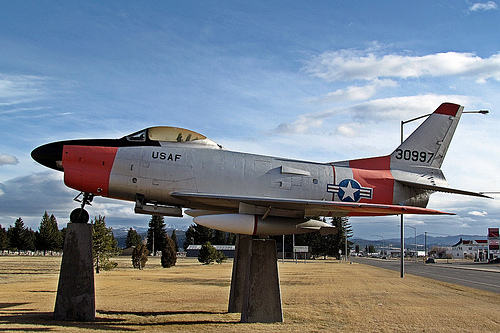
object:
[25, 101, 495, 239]
plane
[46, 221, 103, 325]
pillar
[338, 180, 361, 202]
star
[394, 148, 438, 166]
number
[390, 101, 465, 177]
tail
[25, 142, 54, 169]
nose tip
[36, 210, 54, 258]
tree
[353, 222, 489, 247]
mountains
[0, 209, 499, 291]
background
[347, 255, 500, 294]
road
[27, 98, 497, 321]
display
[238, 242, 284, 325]
column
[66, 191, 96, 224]
front landing gear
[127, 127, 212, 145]
dome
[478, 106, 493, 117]
street light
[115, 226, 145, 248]
mountain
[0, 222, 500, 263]
distance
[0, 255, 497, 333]
park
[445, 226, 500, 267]
town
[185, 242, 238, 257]
barn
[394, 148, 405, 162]
3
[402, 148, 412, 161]
0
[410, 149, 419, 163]
9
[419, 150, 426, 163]
9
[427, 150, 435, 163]
7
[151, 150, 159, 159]
u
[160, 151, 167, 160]
s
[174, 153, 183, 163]
f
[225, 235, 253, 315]
post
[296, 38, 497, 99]
cloud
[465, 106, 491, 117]
post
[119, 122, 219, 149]
cockpit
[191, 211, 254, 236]
nose